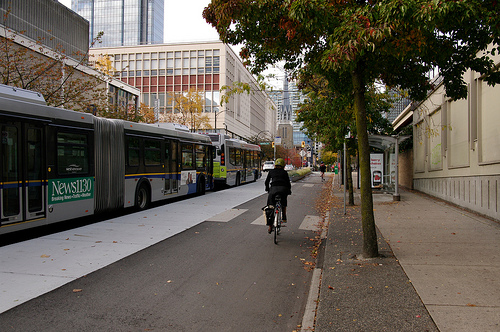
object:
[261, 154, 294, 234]
person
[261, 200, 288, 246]
bicycle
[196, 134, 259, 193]
buses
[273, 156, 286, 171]
hat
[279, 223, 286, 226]
peddle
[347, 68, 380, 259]
trunk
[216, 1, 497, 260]
tree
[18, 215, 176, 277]
sidewalk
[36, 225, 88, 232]
curb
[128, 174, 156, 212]
tire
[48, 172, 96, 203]
billboard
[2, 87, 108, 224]
bus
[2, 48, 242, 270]
street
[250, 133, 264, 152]
light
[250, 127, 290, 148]
lights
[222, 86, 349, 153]
distance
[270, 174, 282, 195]
black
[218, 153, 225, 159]
light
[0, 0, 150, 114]
building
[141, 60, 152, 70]
windows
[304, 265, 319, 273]
leaves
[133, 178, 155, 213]
wheel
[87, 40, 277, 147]
building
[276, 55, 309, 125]
building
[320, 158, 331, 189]
pedestrian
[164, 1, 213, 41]
section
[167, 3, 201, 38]
sky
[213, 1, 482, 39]
tops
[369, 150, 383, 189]
sign